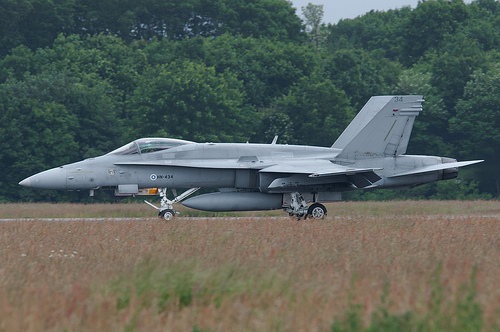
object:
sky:
[286, 0, 420, 38]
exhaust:
[442, 155, 459, 180]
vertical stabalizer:
[334, 94, 426, 159]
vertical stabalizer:
[330, 95, 394, 149]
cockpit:
[109, 136, 194, 157]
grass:
[123, 265, 199, 301]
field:
[0, 201, 500, 332]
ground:
[0, 194, 500, 280]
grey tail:
[329, 93, 426, 160]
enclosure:
[106, 133, 190, 155]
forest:
[1, 43, 32, 168]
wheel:
[307, 202, 329, 221]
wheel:
[160, 209, 176, 222]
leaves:
[307, 85, 314, 90]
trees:
[166, 58, 204, 136]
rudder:
[270, 135, 279, 145]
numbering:
[157, 174, 174, 179]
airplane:
[17, 93, 486, 221]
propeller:
[386, 159, 486, 179]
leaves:
[480, 22, 489, 27]